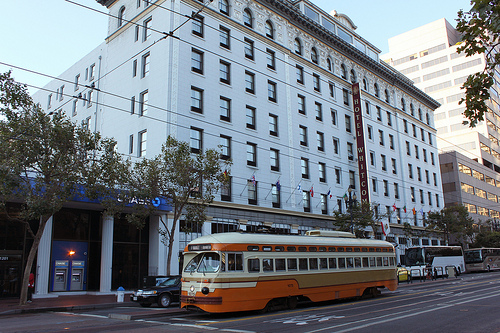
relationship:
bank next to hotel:
[0, 166, 173, 297] [118, 48, 437, 293]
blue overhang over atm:
[5, 147, 199, 231] [44, 244, 93, 296]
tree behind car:
[133, 151, 210, 302] [136, 265, 201, 304]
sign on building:
[350, 82, 372, 218] [14, 1, 452, 283]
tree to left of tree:
[0, 72, 112, 317] [91, 122, 233, 306]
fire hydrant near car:
[114, 285, 126, 304] [129, 274, 180, 308]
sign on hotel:
[348, 75, 376, 216] [3, 0, 445, 278]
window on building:
[218, 94, 232, 124] [1, 0, 450, 238]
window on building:
[264, 51, 277, 70] [1, 0, 450, 238]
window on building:
[269, 185, 283, 210] [1, 0, 450, 238]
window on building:
[243, 142, 257, 165] [1, 0, 450, 238]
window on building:
[267, 111, 278, 135] [1, 0, 450, 238]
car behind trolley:
[127, 272, 184, 308] [178, 225, 400, 317]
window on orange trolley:
[183, 248, 218, 273] [178, 229, 398, 317]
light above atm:
[66, 249, 76, 255] [46, 238, 90, 290]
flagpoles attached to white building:
[263, 178, 283, 204] [2, 0, 443, 285]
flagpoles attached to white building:
[323, 187, 333, 207] [2, 0, 443, 285]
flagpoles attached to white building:
[206, 165, 228, 195] [2, 0, 443, 285]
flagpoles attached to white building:
[283, 176, 302, 206] [2, 0, 443, 285]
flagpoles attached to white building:
[387, 202, 397, 219] [2, 0, 443, 285]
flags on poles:
[215, 157, 450, 224] [213, 162, 445, 222]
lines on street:
[217, 271, 497, 328] [0, 269, 499, 331]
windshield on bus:
[180, 252, 221, 272] [177, 230, 400, 312]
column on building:
[97, 210, 116, 291] [36, 208, 105, 285]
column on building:
[32, 205, 54, 300] [36, 208, 105, 285]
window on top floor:
[241, 4, 253, 23] [0, 0, 440, 122]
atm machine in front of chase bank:
[49, 257, 69, 296] [10, 174, 169, 300]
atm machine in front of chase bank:
[70, 257, 85, 293] [10, 174, 169, 300]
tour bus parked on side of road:
[397, 243, 467, 279] [1, 265, 498, 330]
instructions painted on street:
[267, 304, 346, 331] [0, 269, 499, 331]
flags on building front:
[208, 157, 449, 224] [168, 0, 443, 273]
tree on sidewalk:
[4, 74, 95, 312] [1, 289, 126, 314]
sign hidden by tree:
[150, 195, 173, 210] [130, 138, 222, 288]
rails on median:
[400, 242, 463, 280] [397, 264, 459, 280]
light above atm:
[64, 247, 76, 255] [51, 257, 68, 292]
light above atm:
[64, 247, 76, 255] [68, 260, 85, 290]